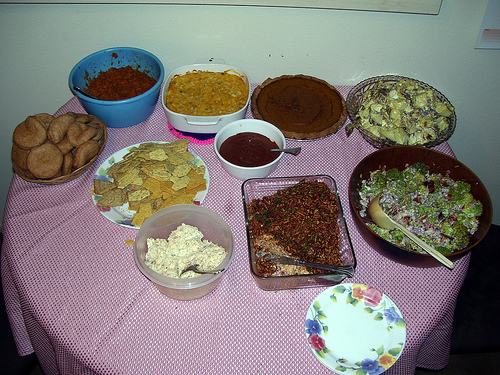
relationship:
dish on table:
[88, 141, 212, 230] [3, 86, 473, 372]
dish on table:
[239, 172, 360, 293] [3, 86, 473, 372]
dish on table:
[127, 204, 236, 300] [3, 86, 473, 372]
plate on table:
[303, 282, 406, 374] [3, 86, 473, 372]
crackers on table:
[85, 140, 210, 227] [3, 86, 473, 372]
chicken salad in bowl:
[139, 219, 224, 281] [128, 201, 238, 304]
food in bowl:
[360, 163, 483, 254] [345, 145, 484, 272]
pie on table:
[248, 74, 348, 140] [3, 86, 473, 372]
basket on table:
[2, 113, 111, 193] [3, 86, 473, 372]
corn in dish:
[168, 70, 247, 115] [161, 62, 250, 134]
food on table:
[239, 172, 358, 292] [3, 86, 473, 372]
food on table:
[91, 137, 213, 228] [3, 86, 473, 372]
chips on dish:
[92, 142, 208, 222] [88, 141, 212, 230]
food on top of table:
[8, 43, 498, 373] [3, 86, 473, 372]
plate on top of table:
[303, 282, 406, 374] [3, 86, 473, 372]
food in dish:
[247, 179, 345, 277] [239, 172, 360, 293]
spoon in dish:
[255, 245, 356, 275] [239, 172, 360, 293]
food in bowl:
[360, 163, 483, 254] [343, 136, 491, 266]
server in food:
[365, 193, 460, 271] [360, 163, 483, 254]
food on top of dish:
[93, 143, 206, 228] [88, 141, 212, 230]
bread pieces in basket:
[9, 111, 107, 180] [11, 111, 109, 187]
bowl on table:
[65, 47, 165, 130] [3, 86, 473, 372]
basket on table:
[11, 111, 109, 187] [3, 86, 473, 372]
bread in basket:
[15, 111, 102, 180] [11, 111, 109, 187]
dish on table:
[157, 62, 251, 139] [3, 86, 473, 372]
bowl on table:
[347, 75, 460, 154] [3, 86, 473, 372]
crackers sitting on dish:
[93, 136, 195, 206] [88, 141, 212, 230]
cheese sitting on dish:
[125, 170, 207, 224] [88, 141, 212, 230]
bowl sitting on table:
[211, 113, 289, 178] [3, 86, 473, 372]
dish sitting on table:
[133, 204, 236, 300] [3, 86, 473, 372]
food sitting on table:
[20, 41, 497, 301] [3, 86, 473, 372]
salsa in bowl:
[81, 66, 154, 101] [65, 47, 165, 130]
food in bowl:
[360, 163, 483, 254] [347, 143, 494, 265]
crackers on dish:
[100, 136, 209, 226] [88, 141, 212, 230]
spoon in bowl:
[271, 140, 302, 158] [212, 120, 289, 183]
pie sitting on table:
[248, 74, 348, 140] [3, 86, 473, 372]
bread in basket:
[15, 111, 102, 180] [11, 113, 109, 191]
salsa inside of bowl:
[232, 130, 262, 155] [213, 120, 286, 178]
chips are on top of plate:
[85, 133, 212, 214] [87, 128, 210, 221]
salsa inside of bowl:
[103, 74, 133, 97] [66, 36, 166, 133]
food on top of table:
[49, 47, 471, 277] [3, 86, 473, 372]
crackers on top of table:
[92, 176, 118, 194] [13, 65, 476, 365]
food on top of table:
[87, 50, 480, 294] [13, 65, 476, 365]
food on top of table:
[82, 60, 488, 263] [13, 65, 476, 365]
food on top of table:
[100, 52, 484, 256] [13, 65, 476, 365]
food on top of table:
[96, 70, 490, 282] [13, 65, 476, 365]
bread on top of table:
[11, 116, 48, 151] [14, 76, 498, 373]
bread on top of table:
[26, 142, 65, 179] [13, 65, 476, 365]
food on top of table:
[175, 62, 427, 152] [3, 86, 473, 372]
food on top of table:
[19, 104, 229, 213] [13, 65, 476, 365]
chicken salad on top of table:
[143, 223, 227, 278] [3, 86, 473, 372]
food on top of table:
[360, 152, 495, 252] [13, 65, 476, 365]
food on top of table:
[352, 77, 452, 127] [13, 65, 476, 365]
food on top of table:
[197, 75, 232, 103] [13, 65, 476, 365]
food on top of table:
[164, 65, 277, 133] [13, 65, 476, 365]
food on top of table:
[93, 143, 206, 228] [13, 65, 476, 365]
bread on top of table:
[11, 104, 97, 174] [13, 65, 476, 365]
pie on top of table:
[248, 74, 348, 140] [13, 65, 476, 365]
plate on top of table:
[311, 278, 405, 368] [13, 65, 476, 365]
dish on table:
[133, 204, 236, 300] [3, 86, 473, 372]